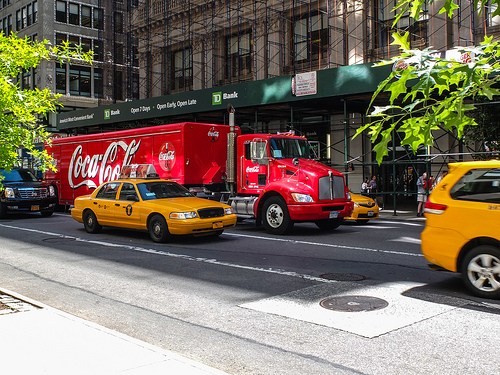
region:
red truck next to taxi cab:
[232, 131, 355, 233]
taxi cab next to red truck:
[67, 162, 238, 244]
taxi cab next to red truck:
[341, 192, 381, 227]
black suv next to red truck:
[1, 164, 59, 220]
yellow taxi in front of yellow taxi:
[419, 161, 498, 299]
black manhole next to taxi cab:
[319, 294, 389, 313]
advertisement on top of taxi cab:
[117, 162, 161, 182]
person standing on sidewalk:
[413, 169, 429, 215]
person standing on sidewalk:
[362, 178, 372, 199]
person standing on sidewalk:
[366, 174, 381, 214]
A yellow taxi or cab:
[69, 179, 237, 241]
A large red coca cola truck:
[43, 121, 353, 236]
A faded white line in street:
[0, 223, 497, 308]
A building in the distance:
[0, 0, 499, 207]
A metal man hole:
[317, 295, 388, 311]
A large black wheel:
[257, 193, 291, 235]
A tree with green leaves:
[0, 26, 96, 194]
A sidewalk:
[0, 289, 240, 374]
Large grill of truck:
[317, 172, 345, 199]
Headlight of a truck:
[287, 190, 314, 202]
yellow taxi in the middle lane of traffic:
[68, 173, 244, 248]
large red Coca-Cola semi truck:
[41, 117, 355, 224]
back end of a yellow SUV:
[413, 150, 498, 296]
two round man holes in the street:
[311, 264, 388, 326]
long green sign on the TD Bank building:
[46, 75, 328, 127]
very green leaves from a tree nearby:
[3, 22, 104, 201]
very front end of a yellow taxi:
[351, 185, 383, 223]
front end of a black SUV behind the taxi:
[2, 165, 60, 221]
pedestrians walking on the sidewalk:
[354, 172, 384, 222]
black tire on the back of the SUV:
[456, 236, 497, 312]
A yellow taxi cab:
[69, 169, 241, 248]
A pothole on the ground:
[317, 288, 392, 319]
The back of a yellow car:
[415, 156, 498, 296]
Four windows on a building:
[52, 0, 106, 36]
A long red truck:
[38, 102, 358, 236]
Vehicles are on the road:
[1, 104, 498, 373]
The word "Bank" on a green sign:
[221, 84, 242, 104]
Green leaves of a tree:
[1, 25, 99, 185]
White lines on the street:
[1, 207, 498, 314]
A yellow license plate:
[207, 215, 227, 233]